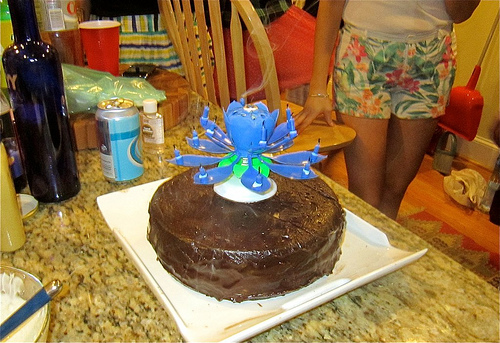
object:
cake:
[144, 158, 347, 304]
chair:
[156, 0, 358, 155]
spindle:
[209, 1, 230, 114]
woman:
[289, 0, 486, 222]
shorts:
[330, 25, 458, 121]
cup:
[77, 19, 120, 78]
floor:
[311, 94, 500, 293]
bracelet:
[307, 93, 330, 97]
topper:
[165, 98, 328, 205]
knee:
[386, 182, 408, 199]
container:
[0, 261, 68, 343]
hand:
[290, 99, 335, 136]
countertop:
[1, 92, 499, 343]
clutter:
[1, 1, 169, 256]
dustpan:
[437, 65, 485, 143]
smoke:
[239, 0, 322, 99]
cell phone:
[122, 63, 157, 78]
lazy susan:
[67, 64, 193, 150]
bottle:
[43, 0, 81, 67]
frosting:
[209, 272, 237, 291]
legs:
[336, 79, 393, 213]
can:
[95, 97, 146, 184]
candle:
[173, 145, 184, 165]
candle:
[192, 128, 200, 146]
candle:
[256, 167, 264, 184]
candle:
[301, 157, 312, 178]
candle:
[286, 104, 292, 120]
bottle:
[140, 99, 164, 149]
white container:
[97, 161, 428, 343]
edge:
[95, 198, 193, 343]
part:
[44, 32, 500, 137]